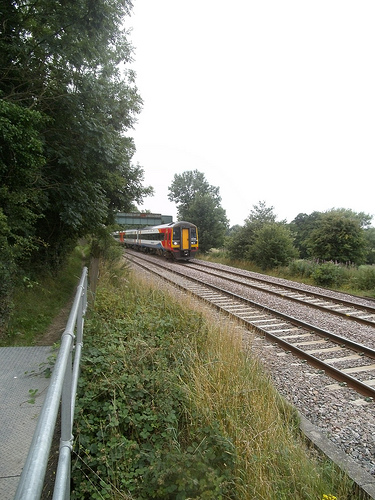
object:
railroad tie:
[277, 332, 316, 339]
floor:
[208, 14, 269, 163]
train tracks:
[186, 255, 335, 339]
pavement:
[0, 346, 60, 500]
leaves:
[0, 16, 147, 255]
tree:
[0, 7, 157, 278]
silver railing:
[11, 263, 90, 500]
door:
[182, 228, 189, 250]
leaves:
[24, 338, 61, 407]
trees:
[166, 167, 375, 293]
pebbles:
[314, 374, 366, 430]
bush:
[285, 258, 375, 292]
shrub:
[68, 259, 237, 500]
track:
[161, 260, 375, 500]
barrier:
[293, 411, 375, 500]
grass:
[75, 250, 352, 500]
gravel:
[281, 363, 316, 390]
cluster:
[322, 492, 340, 499]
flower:
[322, 492, 332, 499]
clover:
[106, 372, 144, 412]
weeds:
[230, 385, 272, 467]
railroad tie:
[258, 322, 288, 327]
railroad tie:
[324, 353, 362, 364]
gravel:
[161, 260, 375, 346]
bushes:
[274, 258, 375, 293]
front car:
[110, 221, 198, 262]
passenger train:
[111, 220, 199, 261]